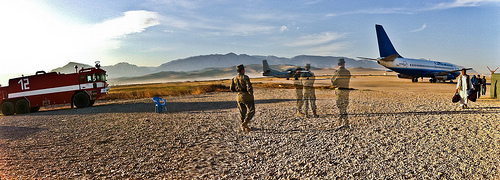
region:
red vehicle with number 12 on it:
[1, 58, 112, 118]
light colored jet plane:
[370, 21, 475, 86]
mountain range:
[15, 54, 438, 86]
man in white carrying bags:
[447, 65, 482, 112]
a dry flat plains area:
[1, 74, 498, 179]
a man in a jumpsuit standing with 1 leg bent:
[224, 65, 261, 135]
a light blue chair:
[147, 94, 171, 114]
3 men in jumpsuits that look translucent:
[286, 55, 364, 131]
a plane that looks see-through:
[259, 58, 306, 85]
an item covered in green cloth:
[487, 71, 499, 106]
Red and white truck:
[5, 59, 122, 143]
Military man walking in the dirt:
[204, 49, 268, 146]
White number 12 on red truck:
[18, 74, 33, 91]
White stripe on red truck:
[2, 82, 124, 107]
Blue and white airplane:
[354, 16, 474, 95]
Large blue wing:
[369, 21, 404, 59]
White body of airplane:
[368, 43, 475, 84]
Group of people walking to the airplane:
[423, 57, 496, 120]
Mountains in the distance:
[43, 43, 398, 94]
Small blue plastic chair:
[137, 77, 179, 130]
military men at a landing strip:
[229, 46, 363, 128]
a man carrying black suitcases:
[451, 62, 481, 107]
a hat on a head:
[232, 62, 244, 71]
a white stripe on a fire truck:
[11, 84, 88, 91]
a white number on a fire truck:
[14, 77, 36, 89]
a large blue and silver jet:
[360, 20, 484, 77]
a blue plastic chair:
[146, 91, 171, 114]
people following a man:
[473, 72, 491, 97]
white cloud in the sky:
[11, 1, 160, 53]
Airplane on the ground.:
[352, 20, 473, 87]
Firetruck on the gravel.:
[2, 60, 112, 112]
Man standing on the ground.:
[225, 55, 267, 134]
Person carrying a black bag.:
[446, 60, 473, 109]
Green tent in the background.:
[488, 70, 498, 100]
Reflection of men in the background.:
[285, 51, 359, 135]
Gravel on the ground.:
[0, 86, 499, 178]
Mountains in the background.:
[43, 48, 385, 84]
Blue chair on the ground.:
[149, 92, 173, 113]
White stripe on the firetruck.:
[5, 75, 107, 102]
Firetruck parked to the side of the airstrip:
[1, 61, 108, 111]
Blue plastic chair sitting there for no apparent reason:
[149, 94, 167, 114]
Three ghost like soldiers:
[291, 60, 356, 130]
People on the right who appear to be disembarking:
[453, 65, 488, 108]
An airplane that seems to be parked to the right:
[353, 21, 473, 81]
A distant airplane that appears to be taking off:
[257, 58, 309, 78]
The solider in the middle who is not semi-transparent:
[229, 61, 256, 132]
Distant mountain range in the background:
[48, 53, 408, 77]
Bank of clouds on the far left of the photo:
[1, 4, 156, 82]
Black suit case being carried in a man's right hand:
[451, 93, 461, 103]